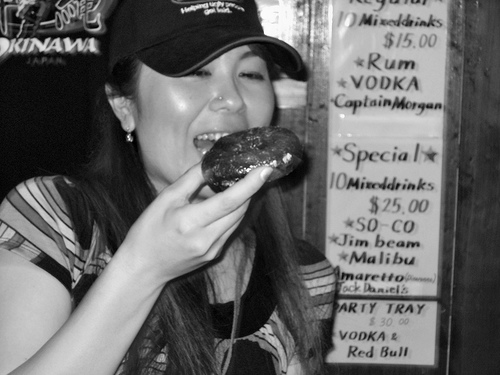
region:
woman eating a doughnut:
[0, 3, 344, 374]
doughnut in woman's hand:
[197, 118, 316, 193]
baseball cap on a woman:
[98, 2, 314, 89]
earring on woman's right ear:
[123, 122, 145, 145]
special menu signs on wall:
[329, 133, 449, 305]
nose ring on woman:
[212, 92, 231, 106]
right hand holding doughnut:
[116, 161, 278, 281]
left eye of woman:
[238, 58, 274, 89]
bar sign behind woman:
[1, 0, 115, 60]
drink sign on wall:
[332, 3, 458, 122]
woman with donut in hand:
[55, 3, 327, 356]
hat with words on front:
[105, 2, 302, 74]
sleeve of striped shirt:
[12, 167, 77, 244]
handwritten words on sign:
[344, 80, 435, 285]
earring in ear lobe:
[117, 118, 146, 150]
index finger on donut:
[244, 152, 284, 189]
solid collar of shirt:
[230, 268, 275, 318]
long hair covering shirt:
[167, 281, 307, 368]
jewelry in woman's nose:
[209, 90, 229, 111]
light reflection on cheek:
[157, 78, 200, 139]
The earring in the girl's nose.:
[209, 92, 229, 104]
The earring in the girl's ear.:
[122, 120, 140, 142]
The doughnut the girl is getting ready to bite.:
[203, 130, 303, 182]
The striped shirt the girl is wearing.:
[7, 176, 335, 366]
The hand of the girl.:
[147, 145, 277, 284]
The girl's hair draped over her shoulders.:
[85, 114, 335, 374]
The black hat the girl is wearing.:
[102, 2, 301, 77]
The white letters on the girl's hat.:
[172, 2, 253, 23]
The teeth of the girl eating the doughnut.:
[194, 130, 239, 155]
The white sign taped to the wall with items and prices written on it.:
[329, 0, 442, 365]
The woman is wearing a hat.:
[90, 0, 323, 196]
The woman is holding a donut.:
[193, 107, 310, 207]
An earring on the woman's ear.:
[115, 117, 141, 148]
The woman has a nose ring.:
[210, 85, 226, 104]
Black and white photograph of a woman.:
[2, 6, 497, 372]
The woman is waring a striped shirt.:
[0, 151, 345, 371]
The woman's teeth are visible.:
[182, 123, 237, 158]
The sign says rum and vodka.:
[331, 45, 437, 93]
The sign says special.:
[330, 130, 440, 166]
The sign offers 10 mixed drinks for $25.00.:
[321, 165, 446, 215]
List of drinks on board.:
[327, 47, 443, 117]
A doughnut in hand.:
[171, 115, 302, 232]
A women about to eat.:
[177, 113, 313, 200]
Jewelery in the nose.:
[216, 91, 225, 103]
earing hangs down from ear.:
[124, 117, 136, 149]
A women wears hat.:
[109, 0, 356, 82]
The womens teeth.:
[198, 131, 224, 141]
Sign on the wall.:
[301, 0, 454, 374]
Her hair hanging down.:
[248, 178, 330, 368]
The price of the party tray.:
[360, 308, 427, 333]